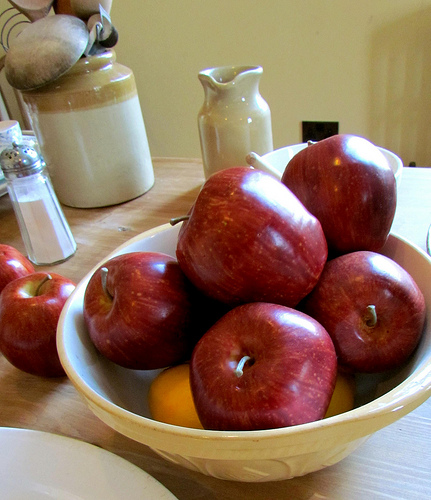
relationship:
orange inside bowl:
[153, 359, 204, 432] [50, 209, 428, 484]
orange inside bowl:
[320, 369, 354, 419] [50, 209, 428, 484]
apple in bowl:
[279, 133, 399, 259] [50, 209, 428, 484]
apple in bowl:
[168, 165, 325, 311] [50, 209, 428, 484]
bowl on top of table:
[50, 209, 428, 484] [2, 155, 429, 500]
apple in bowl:
[82, 252, 200, 370] [50, 209, 428, 484]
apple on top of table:
[0, 273, 75, 379] [2, 155, 429, 500]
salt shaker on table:
[0, 145, 77, 266] [2, 155, 429, 500]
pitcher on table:
[196, 65, 275, 180] [2, 155, 429, 500]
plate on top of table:
[1, 428, 185, 500] [2, 155, 429, 500]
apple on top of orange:
[279, 133, 399, 259] [153, 359, 204, 432]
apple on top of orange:
[168, 165, 325, 311] [153, 359, 204, 432]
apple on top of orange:
[82, 252, 200, 370] [153, 359, 204, 432]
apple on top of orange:
[190, 302, 336, 431] [153, 359, 204, 432]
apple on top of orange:
[307, 251, 427, 372] [320, 369, 354, 419]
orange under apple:
[153, 359, 204, 432] [82, 252, 200, 370]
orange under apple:
[153, 359, 204, 432] [190, 302, 336, 431]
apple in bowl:
[190, 302, 336, 431] [50, 209, 428, 484]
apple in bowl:
[307, 251, 427, 372] [50, 209, 428, 484]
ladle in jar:
[6, 15, 90, 90] [12, 47, 156, 209]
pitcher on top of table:
[196, 65, 275, 180] [2, 155, 429, 500]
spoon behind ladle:
[9, 0, 54, 23] [6, 15, 90, 90]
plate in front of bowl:
[1, 428, 185, 500] [50, 209, 428, 484]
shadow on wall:
[369, 3, 431, 173] [0, 0, 430, 168]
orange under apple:
[320, 369, 354, 419] [307, 251, 427, 372]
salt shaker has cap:
[0, 145, 77, 266] [1, 146, 44, 180]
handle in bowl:
[247, 151, 281, 180] [246, 140, 402, 200]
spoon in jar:
[9, 0, 54, 23] [12, 47, 156, 209]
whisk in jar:
[1, 7, 30, 52] [12, 47, 156, 209]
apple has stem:
[168, 165, 325, 311] [170, 215, 191, 227]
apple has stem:
[82, 252, 200, 370] [99, 268, 112, 302]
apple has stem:
[190, 302, 336, 431] [235, 355, 254, 377]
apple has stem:
[307, 251, 427, 372] [365, 303, 378, 328]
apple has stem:
[0, 273, 75, 379] [34, 273, 50, 297]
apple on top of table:
[0, 242, 35, 294] [2, 155, 429, 500]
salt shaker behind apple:
[0, 145, 77, 266] [0, 242, 35, 294]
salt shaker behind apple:
[0, 145, 77, 266] [0, 273, 75, 379]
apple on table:
[0, 273, 75, 379] [2, 155, 429, 500]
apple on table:
[0, 242, 35, 294] [2, 155, 429, 500]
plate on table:
[1, 428, 185, 500] [2, 155, 429, 500]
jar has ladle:
[12, 47, 156, 209] [6, 15, 90, 90]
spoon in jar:
[75, 0, 113, 22] [12, 47, 156, 209]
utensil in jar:
[86, 6, 119, 58] [12, 47, 156, 209]